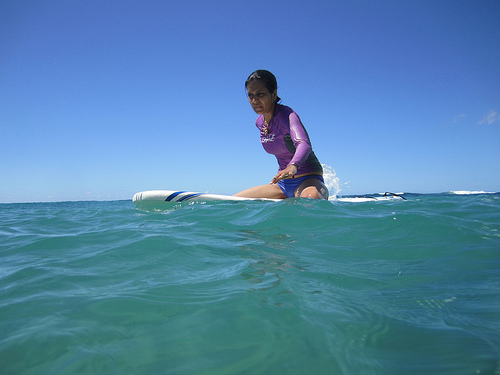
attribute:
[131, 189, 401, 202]
surfboard — blue, white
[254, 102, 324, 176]
top — purple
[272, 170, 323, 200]
bikini bottoms — blue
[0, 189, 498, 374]
ocean — blue, green, open, blue green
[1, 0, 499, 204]
sky — blue, cloudless, clear, beautiful, mostly clear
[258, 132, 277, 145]
writing — white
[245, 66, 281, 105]
hair — black, pulled back, brown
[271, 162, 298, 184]
hand — extended, paddling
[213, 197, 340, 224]
wave — forming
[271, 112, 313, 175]
arm — paddling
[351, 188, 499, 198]
waves — distant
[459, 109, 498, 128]
cloud — white, small